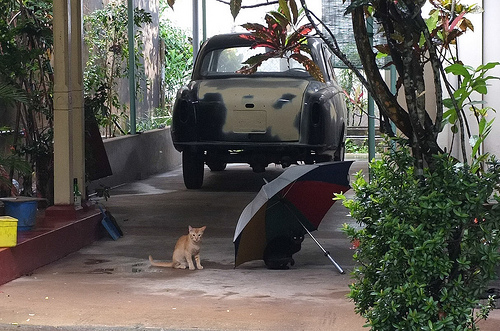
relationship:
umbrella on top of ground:
[233, 161, 355, 273] [0, 157, 499, 330]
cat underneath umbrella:
[263, 230, 304, 269] [233, 161, 355, 273]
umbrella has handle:
[233, 161, 355, 273] [326, 254, 344, 274]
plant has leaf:
[168, 0, 499, 330] [446, 64, 470, 88]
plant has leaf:
[168, 0, 499, 330] [419, 197, 428, 209]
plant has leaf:
[83, 0, 151, 140] [86, 73, 89, 78]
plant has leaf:
[0, 0, 56, 196] [0, 83, 11, 93]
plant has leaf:
[158, 19, 192, 127] [188, 54, 190, 57]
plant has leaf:
[168, 0, 499, 330] [393, 289, 402, 294]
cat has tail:
[149, 225, 207, 270] [149, 255, 173, 266]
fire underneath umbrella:
[263, 230, 304, 269] [233, 161, 355, 273]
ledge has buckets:
[1, 205, 108, 285] [1, 198, 34, 247]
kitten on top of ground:
[149, 225, 207, 270] [0, 157, 499, 330]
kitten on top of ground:
[263, 230, 304, 269] [0, 157, 499, 330]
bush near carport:
[168, 0, 499, 330] [52, 0, 396, 331]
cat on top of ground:
[149, 225, 207, 270] [0, 157, 499, 330]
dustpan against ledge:
[98, 206, 119, 241] [1, 205, 108, 285]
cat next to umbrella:
[149, 225, 207, 270] [233, 161, 355, 273]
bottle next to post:
[74, 179, 82, 212] [53, 0, 87, 204]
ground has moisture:
[0, 157, 499, 330] [90, 179, 174, 200]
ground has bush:
[0, 157, 499, 330] [168, 0, 499, 330]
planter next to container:
[4, 201, 38, 230] [0, 216, 17, 246]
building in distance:
[321, 0, 387, 66] [159, 0, 388, 68]